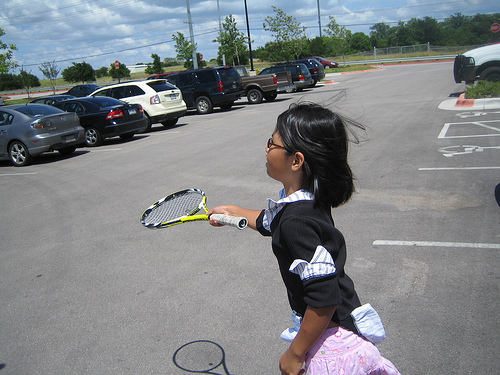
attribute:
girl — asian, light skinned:
[208, 104, 399, 374]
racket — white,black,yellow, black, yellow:
[140, 186, 249, 231]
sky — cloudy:
[2, 2, 500, 78]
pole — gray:
[317, 1, 323, 39]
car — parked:
[2, 101, 87, 167]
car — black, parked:
[53, 96, 147, 147]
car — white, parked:
[84, 78, 187, 132]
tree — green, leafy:
[0, 27, 19, 90]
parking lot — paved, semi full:
[0, 63, 499, 373]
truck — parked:
[231, 65, 295, 105]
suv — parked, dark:
[165, 65, 247, 115]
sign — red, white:
[113, 59, 120, 71]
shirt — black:
[254, 188, 363, 319]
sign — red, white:
[198, 52, 204, 63]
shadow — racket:
[173, 339, 233, 375]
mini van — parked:
[256, 63, 315, 92]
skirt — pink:
[299, 326, 401, 374]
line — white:
[419, 164, 499, 174]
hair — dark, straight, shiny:
[276, 104, 358, 211]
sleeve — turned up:
[280, 216, 343, 310]